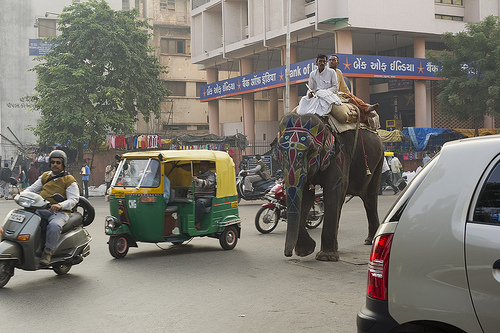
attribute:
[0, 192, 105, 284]
motorcycle — moving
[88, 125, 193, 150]
clothes — hung-up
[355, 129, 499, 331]
car — silver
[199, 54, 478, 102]
sign — blue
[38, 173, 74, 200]
vest — tan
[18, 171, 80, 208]
shirt — white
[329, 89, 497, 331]
car — pale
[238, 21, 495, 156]
building — pale, tall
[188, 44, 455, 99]
sign — blue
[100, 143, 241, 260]
car — yellow, green, small, three-wheel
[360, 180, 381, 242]
leg — standing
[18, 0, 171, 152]
tree leaves — green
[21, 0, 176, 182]
tree — green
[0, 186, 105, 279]
scooter — grey, gas-powered, street-legal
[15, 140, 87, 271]
man — sitting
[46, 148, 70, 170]
helmet — grey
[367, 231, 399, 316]
tail lights — red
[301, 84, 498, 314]
suv — silver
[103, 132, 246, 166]
clothing — colorful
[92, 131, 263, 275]
taxi — yellow, green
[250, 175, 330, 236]
bike — red